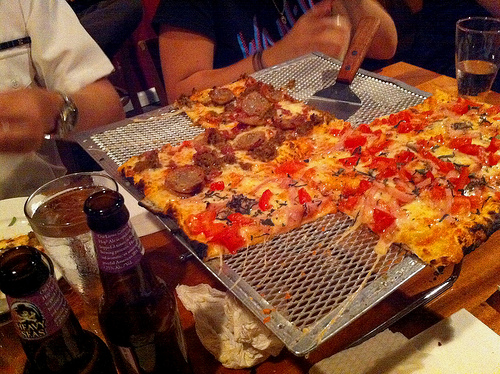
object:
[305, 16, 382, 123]
spatula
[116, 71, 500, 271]
pizza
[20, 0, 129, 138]
arm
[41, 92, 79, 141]
wrist watch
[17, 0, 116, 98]
sleeve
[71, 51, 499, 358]
screen